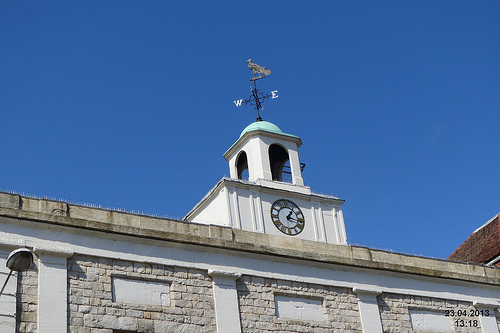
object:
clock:
[271, 199, 305, 236]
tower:
[183, 80, 351, 244]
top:
[181, 88, 349, 245]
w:
[233, 99, 244, 107]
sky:
[2, 6, 200, 180]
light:
[5, 247, 33, 273]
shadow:
[38, 227, 114, 266]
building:
[15, 91, 469, 331]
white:
[210, 197, 336, 246]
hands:
[286, 210, 293, 217]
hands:
[289, 217, 302, 222]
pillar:
[209, 272, 245, 332]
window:
[235, 142, 294, 184]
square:
[275, 290, 329, 322]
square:
[110, 271, 175, 308]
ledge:
[1, 190, 499, 288]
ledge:
[217, 176, 346, 206]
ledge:
[183, 177, 225, 218]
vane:
[231, 57, 280, 122]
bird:
[246, 59, 272, 78]